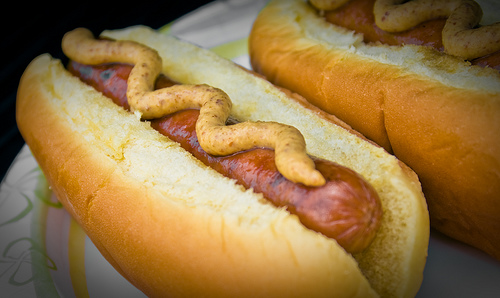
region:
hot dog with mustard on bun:
[16, 21, 431, 296]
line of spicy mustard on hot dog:
[57, 25, 322, 181]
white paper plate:
[2, 0, 494, 292]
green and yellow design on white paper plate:
[3, 206, 94, 294]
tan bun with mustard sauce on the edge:
[31, 80, 144, 213]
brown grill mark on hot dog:
[256, 165, 328, 199]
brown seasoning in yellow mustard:
[134, 58, 154, 83]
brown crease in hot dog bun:
[369, 89, 414, 152]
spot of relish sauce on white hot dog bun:
[412, 41, 468, 85]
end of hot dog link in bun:
[326, 181, 392, 253]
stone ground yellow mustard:
[68, 22, 320, 196]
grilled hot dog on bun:
[73, 30, 369, 246]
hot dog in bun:
[25, 15, 415, 295]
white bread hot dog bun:
[253, 2, 498, 263]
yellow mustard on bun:
[325, 3, 498, 62]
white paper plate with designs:
[1, 4, 499, 290]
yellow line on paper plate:
[60, 217, 97, 296]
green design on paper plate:
[1, 152, 65, 287]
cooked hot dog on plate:
[19, 18, 433, 295]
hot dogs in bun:
[14, 2, 496, 294]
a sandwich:
[41, 18, 423, 289]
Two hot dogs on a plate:
[19, 0, 494, 288]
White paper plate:
[9, 42, 498, 296]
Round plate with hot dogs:
[5, 13, 495, 290]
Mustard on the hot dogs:
[42, 9, 499, 205]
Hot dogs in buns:
[25, 1, 497, 279]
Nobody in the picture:
[3, 19, 497, 294]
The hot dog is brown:
[58, 40, 395, 257]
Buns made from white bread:
[14, 19, 494, 286]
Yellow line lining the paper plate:
[65, 218, 93, 291]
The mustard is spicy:
[55, 14, 344, 201]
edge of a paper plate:
[0, 140, 46, 291]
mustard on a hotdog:
[215, 120, 347, 212]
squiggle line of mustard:
[51, 25, 326, 185]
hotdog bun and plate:
[6, 165, 206, 295]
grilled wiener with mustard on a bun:
[10, 40, 395, 291]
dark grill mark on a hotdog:
[70, 50, 130, 85]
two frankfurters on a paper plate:
[20, 5, 490, 285]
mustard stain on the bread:
[410, 40, 460, 75]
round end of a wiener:
[335, 160, 386, 256]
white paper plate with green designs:
[0, 181, 84, 296]